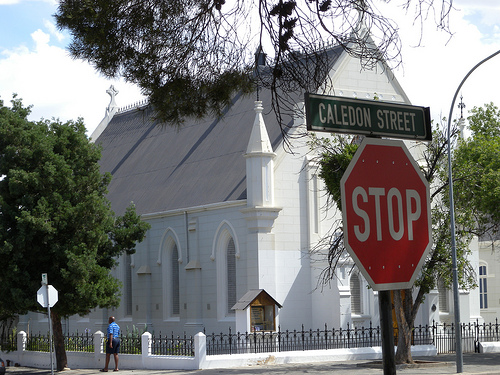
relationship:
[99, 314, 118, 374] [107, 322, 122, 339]
man wearing blue t-shirt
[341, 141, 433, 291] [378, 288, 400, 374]
sign on pole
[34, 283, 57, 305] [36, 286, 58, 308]
back side on sign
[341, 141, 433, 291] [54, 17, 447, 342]
sign by church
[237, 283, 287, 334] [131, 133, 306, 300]
board lists church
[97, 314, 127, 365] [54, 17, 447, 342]
pedestrian walks church